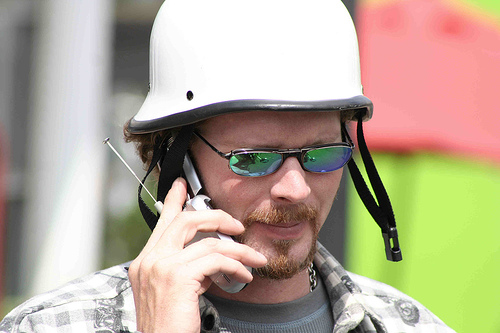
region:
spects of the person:
[204, 141, 366, 182]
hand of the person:
[122, 171, 239, 310]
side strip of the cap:
[343, 135, 428, 267]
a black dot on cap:
[173, 84, 203, 105]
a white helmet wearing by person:
[126, 11, 439, 130]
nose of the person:
[278, 175, 326, 218]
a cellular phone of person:
[150, 158, 260, 280]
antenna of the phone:
[91, 117, 168, 212]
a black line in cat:
[136, 90, 400, 127]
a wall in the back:
[383, 16, 496, 297]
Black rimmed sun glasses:
[193, 127, 365, 179]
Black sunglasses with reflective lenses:
[193, 129, 371, 186]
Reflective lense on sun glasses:
[218, 146, 285, 187]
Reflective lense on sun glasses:
[293, 143, 349, 176]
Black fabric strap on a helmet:
[335, 108, 410, 275]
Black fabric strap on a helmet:
[123, 114, 190, 237]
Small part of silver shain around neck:
[300, 256, 324, 300]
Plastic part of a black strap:
[370, 211, 414, 276]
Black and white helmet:
[98, 1, 403, 136]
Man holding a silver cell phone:
[89, 123, 267, 310]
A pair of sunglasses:
[191, 123, 356, 182]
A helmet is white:
[122, 1, 376, 141]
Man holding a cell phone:
[94, 2, 414, 331]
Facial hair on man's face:
[238, 202, 323, 284]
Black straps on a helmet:
[133, 107, 405, 267]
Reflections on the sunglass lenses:
[228, 143, 353, 180]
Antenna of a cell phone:
[100, 133, 160, 205]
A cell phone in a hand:
[101, 134, 269, 331]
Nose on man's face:
[264, 157, 315, 208]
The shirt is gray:
[202, 280, 336, 331]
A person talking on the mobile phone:
[103, 140, 249, 284]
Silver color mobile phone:
[101, 140, 248, 289]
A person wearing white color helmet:
[146, 15, 381, 120]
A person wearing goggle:
[208, 133, 358, 186]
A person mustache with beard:
[247, 207, 324, 277]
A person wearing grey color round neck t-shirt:
[233, 293, 325, 332]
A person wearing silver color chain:
[306, 265, 318, 287]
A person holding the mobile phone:
[111, 187, 256, 324]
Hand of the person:
[103, 203, 245, 331]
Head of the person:
[114, 24, 432, 281]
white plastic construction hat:
[131, 1, 374, 127]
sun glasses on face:
[199, 130, 355, 178]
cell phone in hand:
[103, 137, 251, 293]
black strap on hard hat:
[340, 115, 405, 265]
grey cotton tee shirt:
[209, 279, 336, 331]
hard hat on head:
[130, 2, 374, 132]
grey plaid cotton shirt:
[4, 238, 456, 332]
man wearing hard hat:
[3, 3, 458, 332]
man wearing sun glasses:
[1, 1, 458, 331]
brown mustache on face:
[244, 205, 317, 225]